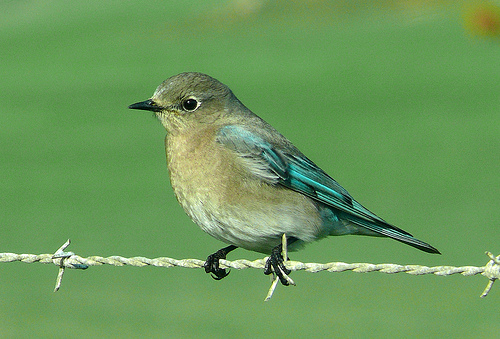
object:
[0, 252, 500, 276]
wires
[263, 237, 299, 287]
leg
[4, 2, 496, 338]
grass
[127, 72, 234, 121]
head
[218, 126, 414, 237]
wing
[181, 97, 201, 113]
eye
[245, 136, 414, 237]
feather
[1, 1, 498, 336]
background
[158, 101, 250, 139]
neck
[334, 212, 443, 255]
tail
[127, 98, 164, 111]
beak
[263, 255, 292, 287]
foot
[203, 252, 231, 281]
foot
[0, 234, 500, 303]
barbed-wire fence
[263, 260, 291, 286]
barb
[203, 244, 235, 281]
black legs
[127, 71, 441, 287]
bird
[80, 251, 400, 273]
wire